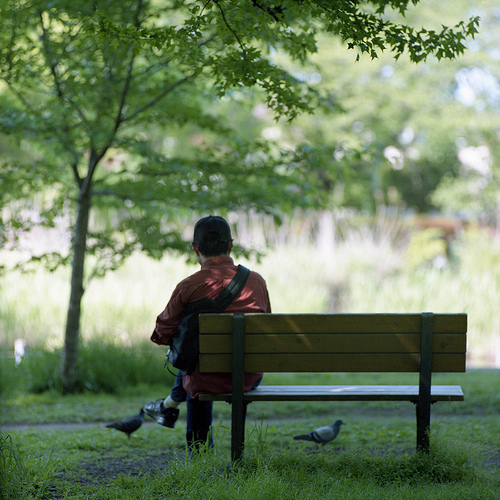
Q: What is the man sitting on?
A: Bench.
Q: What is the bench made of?
A: Wood.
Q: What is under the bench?
A: Bird.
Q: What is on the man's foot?
A: Shoe.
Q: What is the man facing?
A: Tree.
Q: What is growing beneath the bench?
A: Grass.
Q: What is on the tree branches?
A: Leaves.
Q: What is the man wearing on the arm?
A: Backpack.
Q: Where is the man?
A: Park.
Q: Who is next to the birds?
A: The person sitting on the bench.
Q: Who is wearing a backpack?
A: The only person on the bench.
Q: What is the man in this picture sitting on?
A: A bench.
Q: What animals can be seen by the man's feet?
A: Birds.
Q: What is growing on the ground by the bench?
A: Grass.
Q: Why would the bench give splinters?
A: Bench is wooden.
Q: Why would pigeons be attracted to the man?
A: Has food.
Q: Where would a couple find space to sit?
A: On bench.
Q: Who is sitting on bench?
A: Man in red shirt.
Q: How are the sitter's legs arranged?
A: Crossed.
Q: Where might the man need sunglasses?
A: Sunny area ahead.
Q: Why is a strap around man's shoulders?
A: Holds bag.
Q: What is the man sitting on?
A: A bench.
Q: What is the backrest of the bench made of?
A: Wood.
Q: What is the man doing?
A: Sitting on a bench.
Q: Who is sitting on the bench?
A: A man.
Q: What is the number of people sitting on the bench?
A: One.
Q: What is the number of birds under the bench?
A: One.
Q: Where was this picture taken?
A: At a park.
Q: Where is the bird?
A: Under the bench.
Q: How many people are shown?
A: One.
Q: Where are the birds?
A: Ground.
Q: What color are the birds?
A: Gray.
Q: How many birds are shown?
A: Two.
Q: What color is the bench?
A: Yellow.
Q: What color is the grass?
A: Green.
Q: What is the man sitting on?
A: Bench.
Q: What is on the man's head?
A: Hat.